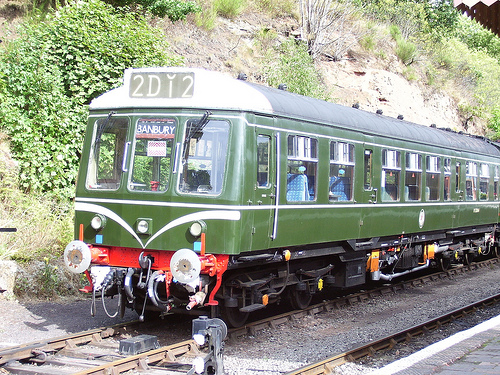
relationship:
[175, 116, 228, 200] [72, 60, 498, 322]
window on train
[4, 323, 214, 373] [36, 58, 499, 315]
rail for train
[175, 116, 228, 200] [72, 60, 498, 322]
window on a train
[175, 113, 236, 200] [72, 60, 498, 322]
window on a train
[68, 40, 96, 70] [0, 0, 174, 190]
leaves on tree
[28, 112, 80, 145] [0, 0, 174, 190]
leaves on tree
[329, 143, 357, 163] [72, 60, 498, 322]
window on train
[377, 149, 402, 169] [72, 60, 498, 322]
window on train